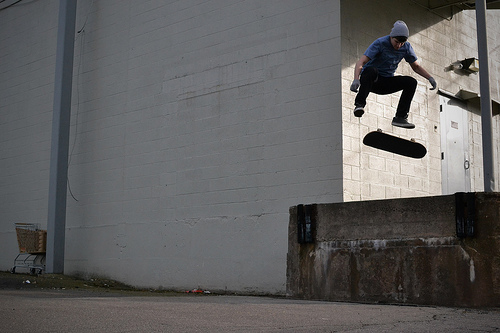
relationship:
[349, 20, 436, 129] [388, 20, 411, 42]
boy wearing beanie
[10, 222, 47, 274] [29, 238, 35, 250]
shopping cart has plastic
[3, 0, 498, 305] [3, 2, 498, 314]
wall has white brick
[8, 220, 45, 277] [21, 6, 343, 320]
shopping cart near building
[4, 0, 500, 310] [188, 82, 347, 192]
building made of blocks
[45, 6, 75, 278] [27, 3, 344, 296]
pole next to building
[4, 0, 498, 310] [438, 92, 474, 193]
building has door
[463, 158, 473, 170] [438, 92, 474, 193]
handle on door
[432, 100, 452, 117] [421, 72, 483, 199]
hinge on door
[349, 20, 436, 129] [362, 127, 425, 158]
boy on a skateboard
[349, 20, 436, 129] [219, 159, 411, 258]
boy in air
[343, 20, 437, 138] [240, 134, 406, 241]
boy in air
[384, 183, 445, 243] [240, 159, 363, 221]
ground in air